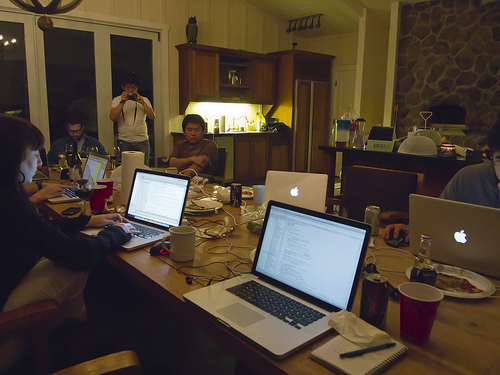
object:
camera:
[126, 92, 138, 100]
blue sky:
[107, 80, 157, 151]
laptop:
[76, 169, 193, 256]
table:
[382, 256, 402, 271]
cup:
[397, 280, 445, 343]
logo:
[451, 229, 467, 246]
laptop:
[408, 193, 500, 278]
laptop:
[262, 170, 329, 223]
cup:
[88, 184, 108, 213]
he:
[110, 73, 157, 170]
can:
[230, 183, 242, 207]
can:
[364, 204, 380, 235]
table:
[462, 327, 493, 370]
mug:
[161, 225, 196, 263]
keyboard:
[226, 279, 327, 331]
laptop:
[184, 201, 374, 358]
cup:
[96, 177, 115, 199]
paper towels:
[108, 149, 153, 206]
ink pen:
[338, 342, 398, 359]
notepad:
[306, 317, 412, 374]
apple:
[290, 185, 299, 197]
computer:
[263, 170, 328, 212]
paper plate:
[403, 263, 497, 299]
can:
[358, 272, 391, 327]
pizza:
[433, 272, 484, 294]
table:
[138, 258, 176, 271]